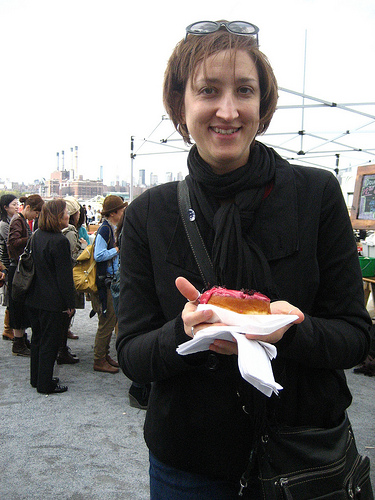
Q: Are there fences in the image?
A: No, there are no fences.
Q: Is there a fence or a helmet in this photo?
A: No, there are no fences or helmets.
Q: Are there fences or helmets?
A: No, there are no fences or helmets.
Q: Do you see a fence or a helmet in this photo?
A: No, there are no fences or helmets.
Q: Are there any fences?
A: No, there are no fences.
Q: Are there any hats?
A: Yes, there is a hat.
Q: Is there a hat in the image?
A: Yes, there is a hat.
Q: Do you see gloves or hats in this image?
A: Yes, there is a hat.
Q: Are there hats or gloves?
A: Yes, there is a hat.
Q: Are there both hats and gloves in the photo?
A: No, there is a hat but no gloves.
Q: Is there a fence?
A: No, there are no fences.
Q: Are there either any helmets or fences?
A: No, there are no fences or helmets.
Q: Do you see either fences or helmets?
A: No, there are no fences or helmets.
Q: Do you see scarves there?
A: Yes, there is a scarf.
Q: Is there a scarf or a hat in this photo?
A: Yes, there is a scarf.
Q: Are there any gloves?
A: No, there are no gloves.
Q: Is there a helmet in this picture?
A: No, there are no helmets.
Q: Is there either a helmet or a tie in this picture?
A: No, there are no helmets or ties.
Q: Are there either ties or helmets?
A: No, there are no helmets or ties.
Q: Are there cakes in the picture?
A: Yes, there is a cake.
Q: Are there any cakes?
A: Yes, there is a cake.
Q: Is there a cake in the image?
A: Yes, there is a cake.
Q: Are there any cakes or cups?
A: Yes, there is a cake.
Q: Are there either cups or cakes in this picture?
A: Yes, there is a cake.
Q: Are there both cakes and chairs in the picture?
A: No, there is a cake but no chairs.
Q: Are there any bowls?
A: No, there are no bowls.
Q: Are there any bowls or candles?
A: No, there are no bowls or candles.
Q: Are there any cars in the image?
A: No, there are no cars.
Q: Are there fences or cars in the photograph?
A: No, there are no cars or fences.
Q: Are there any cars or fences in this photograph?
A: No, there are no cars or fences.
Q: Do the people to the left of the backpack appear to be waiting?
A: Yes, the people are waiting.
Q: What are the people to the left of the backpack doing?
A: The people are waiting.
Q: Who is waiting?
A: The people are waiting.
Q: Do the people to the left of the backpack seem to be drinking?
A: No, the people are waiting.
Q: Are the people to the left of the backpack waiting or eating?
A: The people are waiting.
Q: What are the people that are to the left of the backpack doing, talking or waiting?
A: The people are waiting.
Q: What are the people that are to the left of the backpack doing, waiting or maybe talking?
A: The people are waiting.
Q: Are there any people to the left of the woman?
A: Yes, there are people to the left of the woman.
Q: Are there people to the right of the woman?
A: No, the people are to the left of the woman.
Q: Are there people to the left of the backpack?
A: Yes, there are people to the left of the backpack.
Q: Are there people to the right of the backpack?
A: No, the people are to the left of the backpack.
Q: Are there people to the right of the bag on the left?
A: No, the people are to the left of the backpack.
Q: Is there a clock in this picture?
A: No, there are no clocks.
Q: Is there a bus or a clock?
A: No, there are no clocks or buses.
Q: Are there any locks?
A: No, there are no locks.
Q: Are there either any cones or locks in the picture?
A: No, there are no locks or cones.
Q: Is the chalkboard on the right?
A: Yes, the chalkboard is on the right of the image.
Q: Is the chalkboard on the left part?
A: No, the chalkboard is on the right of the image.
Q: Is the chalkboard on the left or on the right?
A: The chalkboard is on the right of the image.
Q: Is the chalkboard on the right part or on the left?
A: The chalkboard is on the right of the image.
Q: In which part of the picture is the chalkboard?
A: The chalkboard is on the right of the image.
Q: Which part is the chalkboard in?
A: The chalkboard is on the right of the image.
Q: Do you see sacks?
A: No, there are no sacks.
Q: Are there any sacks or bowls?
A: No, there are no sacks or bowls.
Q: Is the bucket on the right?
A: Yes, the bucket is on the right of the image.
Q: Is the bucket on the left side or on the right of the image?
A: The bucket is on the right of the image.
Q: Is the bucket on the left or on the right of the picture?
A: The bucket is on the right of the image.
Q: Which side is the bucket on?
A: The bucket is on the right of the image.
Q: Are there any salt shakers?
A: No, there are no salt shakers.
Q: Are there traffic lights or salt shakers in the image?
A: No, there are no salt shakers or traffic lights.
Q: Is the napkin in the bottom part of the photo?
A: Yes, the napkin is in the bottom of the image.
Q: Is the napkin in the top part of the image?
A: No, the napkin is in the bottom of the image.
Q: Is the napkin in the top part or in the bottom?
A: The napkin is in the bottom of the image.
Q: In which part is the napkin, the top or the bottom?
A: The napkin is in the bottom of the image.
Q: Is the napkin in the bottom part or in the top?
A: The napkin is in the bottom of the image.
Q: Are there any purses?
A: Yes, there is a purse.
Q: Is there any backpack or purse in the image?
A: Yes, there is a purse.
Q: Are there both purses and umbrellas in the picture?
A: No, there is a purse but no umbrellas.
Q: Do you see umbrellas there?
A: No, there are no umbrellas.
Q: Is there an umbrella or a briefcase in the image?
A: No, there are no umbrellas or briefcases.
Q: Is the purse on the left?
A: No, the purse is on the right of the image.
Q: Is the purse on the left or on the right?
A: The purse is on the right of the image.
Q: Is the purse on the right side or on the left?
A: The purse is on the right of the image.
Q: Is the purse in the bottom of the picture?
A: Yes, the purse is in the bottom of the image.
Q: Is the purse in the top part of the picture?
A: No, the purse is in the bottom of the image.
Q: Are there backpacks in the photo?
A: Yes, there is a backpack.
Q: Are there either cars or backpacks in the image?
A: Yes, there is a backpack.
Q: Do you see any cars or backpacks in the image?
A: Yes, there is a backpack.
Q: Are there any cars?
A: No, there are no cars.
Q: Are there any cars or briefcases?
A: No, there are no cars or briefcases.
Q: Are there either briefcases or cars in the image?
A: No, there are no cars or briefcases.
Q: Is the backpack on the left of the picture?
A: Yes, the backpack is on the left of the image.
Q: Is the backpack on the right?
A: No, the backpack is on the left of the image.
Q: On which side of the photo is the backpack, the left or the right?
A: The backpack is on the left of the image.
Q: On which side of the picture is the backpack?
A: The backpack is on the left of the image.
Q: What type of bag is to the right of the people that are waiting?
A: The bag is a backpack.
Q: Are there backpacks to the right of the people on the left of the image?
A: Yes, there is a backpack to the right of the people.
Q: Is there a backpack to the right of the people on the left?
A: Yes, there is a backpack to the right of the people.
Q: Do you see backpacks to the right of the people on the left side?
A: Yes, there is a backpack to the right of the people.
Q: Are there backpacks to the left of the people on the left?
A: No, the backpack is to the right of the people.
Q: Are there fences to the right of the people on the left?
A: No, there is a backpack to the right of the people.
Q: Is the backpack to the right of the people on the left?
A: Yes, the backpack is to the right of the people.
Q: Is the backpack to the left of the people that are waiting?
A: No, the backpack is to the right of the people.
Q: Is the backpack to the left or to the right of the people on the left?
A: The backpack is to the right of the people.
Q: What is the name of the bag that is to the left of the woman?
A: The bag is a backpack.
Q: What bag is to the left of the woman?
A: The bag is a backpack.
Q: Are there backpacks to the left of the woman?
A: Yes, there is a backpack to the left of the woman.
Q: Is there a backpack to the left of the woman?
A: Yes, there is a backpack to the left of the woman.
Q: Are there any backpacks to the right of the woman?
A: No, the backpack is to the left of the woman.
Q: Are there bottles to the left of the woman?
A: No, there is a backpack to the left of the woman.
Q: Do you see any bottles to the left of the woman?
A: No, there is a backpack to the left of the woman.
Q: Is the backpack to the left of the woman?
A: Yes, the backpack is to the left of the woman.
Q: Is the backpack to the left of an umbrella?
A: No, the backpack is to the left of the woman.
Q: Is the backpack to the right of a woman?
A: No, the backpack is to the left of a woman.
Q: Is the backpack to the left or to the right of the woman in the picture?
A: The backpack is to the left of the woman.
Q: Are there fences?
A: No, there are no fences.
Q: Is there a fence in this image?
A: No, there are no fences.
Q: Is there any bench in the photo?
A: No, there are no benches.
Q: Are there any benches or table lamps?
A: No, there are no benches or table lamps.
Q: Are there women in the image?
A: Yes, there is a woman.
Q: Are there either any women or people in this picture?
A: Yes, there is a woman.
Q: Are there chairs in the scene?
A: No, there are no chairs.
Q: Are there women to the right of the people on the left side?
A: Yes, there is a woman to the right of the people.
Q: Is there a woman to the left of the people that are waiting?
A: No, the woman is to the right of the people.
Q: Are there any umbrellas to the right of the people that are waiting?
A: No, there is a woman to the right of the people.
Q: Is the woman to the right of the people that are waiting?
A: Yes, the woman is to the right of the people.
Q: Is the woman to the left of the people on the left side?
A: No, the woman is to the right of the people.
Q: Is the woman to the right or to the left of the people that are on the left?
A: The woman is to the right of the people.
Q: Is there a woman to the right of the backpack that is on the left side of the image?
A: Yes, there is a woman to the right of the backpack.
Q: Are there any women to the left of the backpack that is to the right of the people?
A: No, the woman is to the right of the backpack.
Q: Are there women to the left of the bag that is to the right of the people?
A: No, the woman is to the right of the backpack.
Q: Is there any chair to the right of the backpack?
A: No, there is a woman to the right of the backpack.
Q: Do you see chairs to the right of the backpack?
A: No, there is a woman to the right of the backpack.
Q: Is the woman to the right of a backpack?
A: Yes, the woman is to the right of a backpack.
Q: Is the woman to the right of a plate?
A: No, the woman is to the right of a backpack.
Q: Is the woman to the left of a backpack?
A: No, the woman is to the right of a backpack.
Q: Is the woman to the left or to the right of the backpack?
A: The woman is to the right of the backpack.